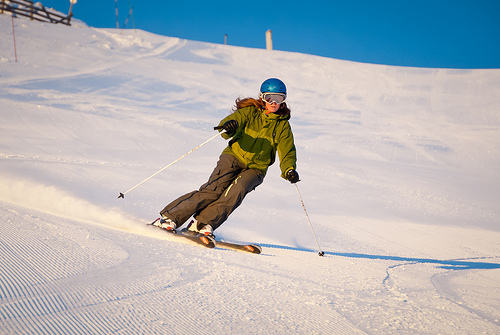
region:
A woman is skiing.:
[116, 78, 321, 255]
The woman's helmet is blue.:
[260, 77, 287, 94]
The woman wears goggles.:
[260, 92, 287, 103]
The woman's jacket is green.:
[215, 106, 300, 171]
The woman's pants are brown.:
[157, 165, 258, 223]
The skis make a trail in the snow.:
[2, 173, 108, 229]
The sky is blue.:
[301, 0, 498, 45]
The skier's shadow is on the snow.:
[340, 250, 496, 272]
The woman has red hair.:
[232, 96, 262, 109]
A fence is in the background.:
[0, 0, 55, 21]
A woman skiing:
[143, 73, 312, 255]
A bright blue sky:
[49, 3, 496, 74]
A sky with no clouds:
[55, 2, 497, 72]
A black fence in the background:
[0, 0, 80, 30]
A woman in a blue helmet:
[259, 76, 288, 102]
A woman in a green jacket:
[214, 103, 299, 179]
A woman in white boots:
[155, 212, 218, 236]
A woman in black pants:
[157, 154, 269, 229]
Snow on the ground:
[0, 8, 498, 329]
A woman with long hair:
[232, 94, 293, 112]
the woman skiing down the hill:
[116, 77, 325, 259]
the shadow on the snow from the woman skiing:
[226, 242, 498, 271]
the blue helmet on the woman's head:
[261, 77, 286, 93]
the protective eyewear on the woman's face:
[258, 91, 288, 103]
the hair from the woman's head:
[232, 95, 289, 115]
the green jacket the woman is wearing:
[218, 105, 297, 180]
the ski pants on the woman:
[159, 148, 268, 229]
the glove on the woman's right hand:
[222, 120, 239, 132]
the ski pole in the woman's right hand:
[113, 118, 238, 198]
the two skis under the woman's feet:
[143, 218, 261, 253]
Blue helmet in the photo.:
[264, 74, 291, 93]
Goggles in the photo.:
[259, 90, 292, 106]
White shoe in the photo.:
[161, 215, 176, 230]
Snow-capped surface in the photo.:
[347, 120, 448, 221]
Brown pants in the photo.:
[175, 175, 248, 213]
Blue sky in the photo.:
[334, 6, 396, 34]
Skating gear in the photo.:
[153, 230, 226, 248]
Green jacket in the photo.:
[235, 121, 272, 179]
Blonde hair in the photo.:
[234, 92, 264, 109]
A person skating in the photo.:
[120, 66, 326, 261]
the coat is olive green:
[251, 124, 273, 162]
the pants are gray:
[217, 156, 236, 186]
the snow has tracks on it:
[378, 241, 469, 316]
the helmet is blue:
[262, 78, 289, 94]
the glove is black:
[282, 167, 302, 192]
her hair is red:
[232, 91, 263, 114]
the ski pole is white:
[169, 140, 204, 170]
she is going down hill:
[218, 71, 303, 220]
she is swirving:
[206, 88, 279, 258]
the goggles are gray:
[258, 86, 288, 106]